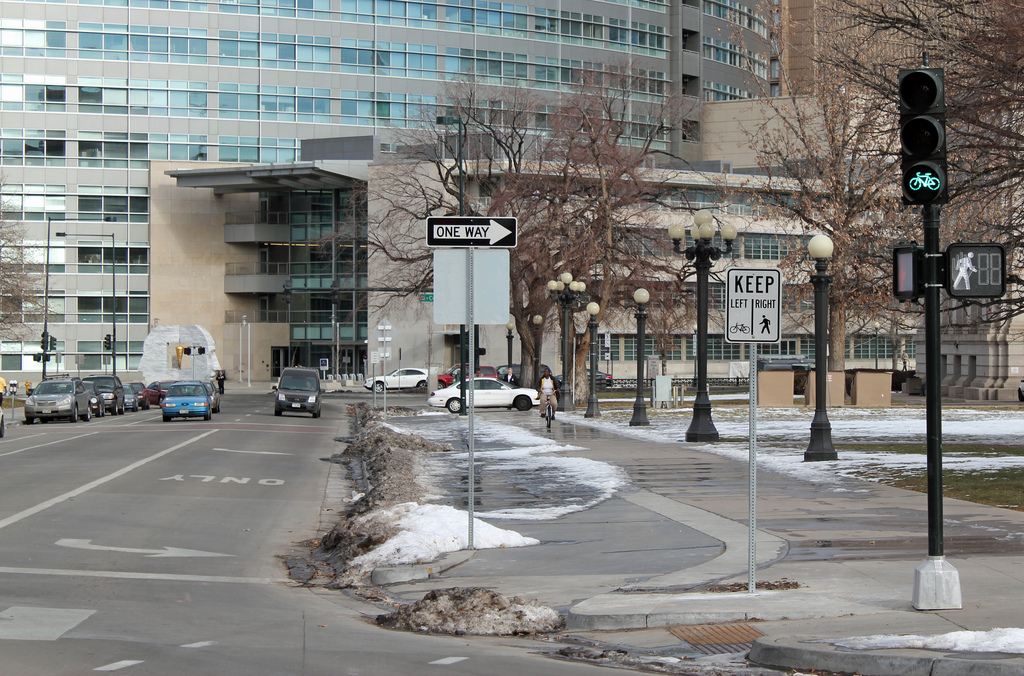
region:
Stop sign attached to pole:
[895, 62, 954, 222]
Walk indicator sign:
[940, 238, 1010, 306]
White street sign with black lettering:
[725, 262, 784, 346]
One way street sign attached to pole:
[424, 211, 520, 250]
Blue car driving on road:
[160, 374, 219, 428]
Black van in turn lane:
[266, 358, 328, 417]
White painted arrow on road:
[58, 527, 233, 566]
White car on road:
[431, 374, 543, 417]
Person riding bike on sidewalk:
[535, 369, 567, 440]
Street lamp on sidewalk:
[798, 227, 847, 468]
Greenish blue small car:
[160, 374, 218, 423]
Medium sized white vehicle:
[366, 364, 442, 391]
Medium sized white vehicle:
[426, 368, 543, 411]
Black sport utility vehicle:
[274, 355, 332, 420]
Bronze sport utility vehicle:
[20, 374, 100, 425]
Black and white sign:
[426, 203, 522, 255]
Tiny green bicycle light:
[893, 162, 950, 197]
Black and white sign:
[731, 266, 789, 344]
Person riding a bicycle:
[526, 361, 571, 434]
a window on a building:
[384, 51, 401, 80]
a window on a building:
[403, 45, 424, 74]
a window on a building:
[433, 48, 459, 86]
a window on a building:
[480, 43, 509, 89]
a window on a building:
[545, 59, 574, 89]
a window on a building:
[589, 70, 602, 81]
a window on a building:
[618, 72, 631, 80]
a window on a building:
[643, 82, 659, 92]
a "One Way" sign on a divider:
[426, 216, 519, 242]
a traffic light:
[891, 69, 946, 202]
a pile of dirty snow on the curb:
[376, 590, 561, 639]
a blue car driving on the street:
[158, 380, 213, 420]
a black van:
[271, 364, 323, 418]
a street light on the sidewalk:
[666, 197, 743, 444]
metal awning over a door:
[164, 162, 374, 189]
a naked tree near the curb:
[354, 61, 700, 425]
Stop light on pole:
[892, 62, 957, 214]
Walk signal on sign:
[943, 236, 1010, 307]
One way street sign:
[428, 210, 515, 253]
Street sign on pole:
[725, 261, 783, 590]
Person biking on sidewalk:
[530, 363, 562, 431]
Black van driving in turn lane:
[270, 362, 331, 427]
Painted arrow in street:
[52, 529, 233, 567]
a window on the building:
[365, 54, 403, 86]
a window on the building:
[283, 57, 306, 74]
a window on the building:
[266, 72, 286, 118]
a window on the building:
[119, 77, 130, 88]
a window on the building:
[234, 130, 260, 150]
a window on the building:
[298, 31, 350, 89]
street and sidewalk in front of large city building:
[28, 13, 1000, 656]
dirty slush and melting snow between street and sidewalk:
[286, 399, 789, 634]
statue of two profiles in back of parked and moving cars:
[24, 319, 323, 425]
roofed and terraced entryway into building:
[150, 158, 367, 390]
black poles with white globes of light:
[521, 199, 845, 460]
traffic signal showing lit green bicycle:
[900, 65, 945, 205]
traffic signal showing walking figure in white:
[937, 244, 1011, 296]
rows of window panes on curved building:
[5, 7, 677, 135]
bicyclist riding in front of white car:
[425, 364, 565, 434]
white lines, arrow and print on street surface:
[8, 396, 345, 663]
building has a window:
[317, 34, 330, 63]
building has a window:
[410, 47, 426, 73]